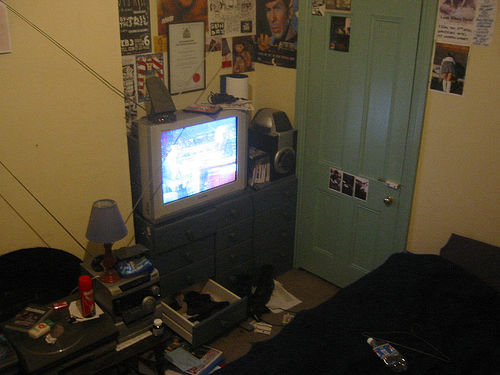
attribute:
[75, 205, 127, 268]
lamp — blue, small, purple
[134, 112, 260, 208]
television — analog, silver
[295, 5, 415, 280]
door — pale blue, closed, blue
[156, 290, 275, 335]
drawer — open, pulled out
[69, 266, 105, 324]
can — red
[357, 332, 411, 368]
bottle — empty, small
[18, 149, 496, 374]
bedroom — messy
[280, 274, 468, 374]
blanket — dark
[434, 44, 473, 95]
picture — girl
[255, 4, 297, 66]
poster — spock